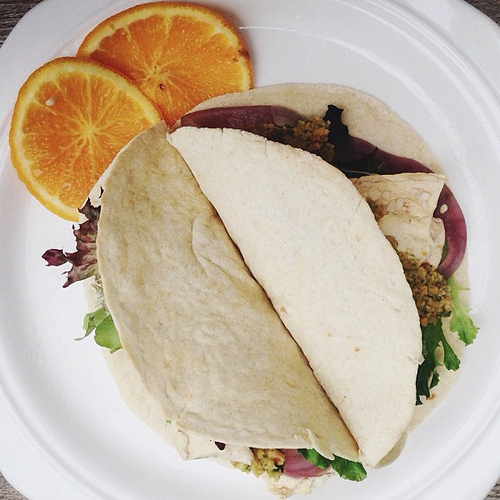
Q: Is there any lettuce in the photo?
A: Yes, there is lettuce.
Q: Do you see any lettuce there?
A: Yes, there is lettuce.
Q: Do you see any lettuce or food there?
A: Yes, there is lettuce.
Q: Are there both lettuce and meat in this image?
A: Yes, there are both lettuce and meat.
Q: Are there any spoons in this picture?
A: No, there are no spoons.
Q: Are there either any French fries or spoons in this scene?
A: No, there are no spoons or French fries.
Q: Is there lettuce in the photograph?
A: Yes, there is lettuce.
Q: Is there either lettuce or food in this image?
A: Yes, there is lettuce.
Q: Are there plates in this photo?
A: Yes, there is a plate.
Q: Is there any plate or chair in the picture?
A: Yes, there is a plate.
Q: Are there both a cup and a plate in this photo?
A: No, there is a plate but no cups.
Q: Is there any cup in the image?
A: No, there are no cups.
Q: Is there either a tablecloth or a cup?
A: No, there are no cups or tablecloths.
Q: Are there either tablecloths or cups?
A: No, there are no cups or tablecloths.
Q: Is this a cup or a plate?
A: This is a plate.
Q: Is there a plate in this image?
A: Yes, there is a plate.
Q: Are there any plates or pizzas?
A: Yes, there is a plate.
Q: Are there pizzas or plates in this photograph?
A: Yes, there is a plate.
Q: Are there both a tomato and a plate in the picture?
A: No, there is a plate but no tomatoes.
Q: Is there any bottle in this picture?
A: No, there are no bottles.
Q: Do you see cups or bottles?
A: No, there are no bottles or cups.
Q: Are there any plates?
A: Yes, there is a plate.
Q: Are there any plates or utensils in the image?
A: Yes, there is a plate.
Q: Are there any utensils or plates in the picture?
A: Yes, there is a plate.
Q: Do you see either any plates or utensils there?
A: Yes, there is a plate.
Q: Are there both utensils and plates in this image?
A: No, there is a plate but no utensils.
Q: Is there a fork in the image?
A: No, there are no forks.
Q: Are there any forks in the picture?
A: No, there are no forks.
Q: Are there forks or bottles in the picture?
A: No, there are no forks or bottles.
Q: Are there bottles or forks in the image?
A: No, there are no forks or bottles.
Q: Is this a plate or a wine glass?
A: This is a plate.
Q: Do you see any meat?
A: Yes, there is meat.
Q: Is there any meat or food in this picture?
A: Yes, there is meat.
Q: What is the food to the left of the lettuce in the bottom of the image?
A: The food is meat.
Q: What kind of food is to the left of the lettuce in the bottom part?
A: The food is meat.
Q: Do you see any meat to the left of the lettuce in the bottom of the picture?
A: Yes, there is meat to the left of the lettuce.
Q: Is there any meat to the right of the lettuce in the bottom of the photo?
A: No, the meat is to the left of the lettuce.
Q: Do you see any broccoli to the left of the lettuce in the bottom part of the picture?
A: No, there is meat to the left of the lettuce.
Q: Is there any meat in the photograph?
A: Yes, there is meat.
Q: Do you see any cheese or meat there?
A: Yes, there is meat.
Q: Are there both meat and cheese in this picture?
A: No, there is meat but no cheese.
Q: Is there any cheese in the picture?
A: No, there is no cheese.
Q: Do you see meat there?
A: Yes, there is meat.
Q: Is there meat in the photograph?
A: Yes, there is meat.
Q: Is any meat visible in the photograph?
A: Yes, there is meat.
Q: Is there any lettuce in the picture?
A: Yes, there is lettuce.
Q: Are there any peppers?
A: No, there are no peppers.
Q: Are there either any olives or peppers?
A: No, there are no peppers or olives.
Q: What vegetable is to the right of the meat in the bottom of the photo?
A: The vegetable is lettuce.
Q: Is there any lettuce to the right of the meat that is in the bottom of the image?
A: Yes, there is lettuce to the right of the meat.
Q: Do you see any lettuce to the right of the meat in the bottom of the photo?
A: Yes, there is lettuce to the right of the meat.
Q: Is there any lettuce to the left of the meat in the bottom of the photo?
A: No, the lettuce is to the right of the meat.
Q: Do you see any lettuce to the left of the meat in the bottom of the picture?
A: No, the lettuce is to the right of the meat.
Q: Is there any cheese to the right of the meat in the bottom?
A: No, there is lettuce to the right of the meat.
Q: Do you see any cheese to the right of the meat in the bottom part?
A: No, there is lettuce to the right of the meat.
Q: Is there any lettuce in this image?
A: Yes, there is lettuce.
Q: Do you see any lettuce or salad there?
A: Yes, there is lettuce.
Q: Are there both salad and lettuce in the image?
A: No, there is lettuce but no salad.